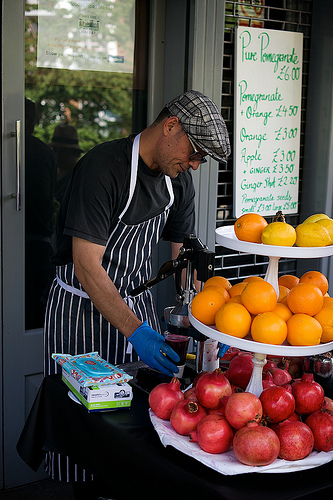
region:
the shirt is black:
[77, 162, 122, 235]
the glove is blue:
[127, 328, 184, 377]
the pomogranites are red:
[179, 373, 308, 462]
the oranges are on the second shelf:
[205, 276, 330, 344]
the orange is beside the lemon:
[224, 202, 295, 249]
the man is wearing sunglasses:
[184, 134, 213, 163]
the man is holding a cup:
[166, 331, 191, 368]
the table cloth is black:
[64, 409, 134, 458]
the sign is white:
[232, 21, 300, 214]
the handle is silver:
[0, 111, 29, 217]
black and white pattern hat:
[172, 91, 232, 162]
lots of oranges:
[200, 275, 331, 328]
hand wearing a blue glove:
[102, 309, 185, 371]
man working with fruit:
[109, 85, 195, 294]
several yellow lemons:
[277, 218, 332, 238]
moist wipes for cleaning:
[48, 349, 132, 391]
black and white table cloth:
[33, 385, 173, 489]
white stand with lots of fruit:
[206, 203, 319, 486]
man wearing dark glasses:
[154, 110, 220, 176]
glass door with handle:
[12, 29, 94, 239]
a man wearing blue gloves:
[128, 319, 179, 378]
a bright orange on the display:
[235, 212, 267, 242]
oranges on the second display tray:
[191, 269, 331, 342]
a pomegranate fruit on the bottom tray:
[145, 350, 328, 471]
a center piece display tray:
[145, 207, 326, 467]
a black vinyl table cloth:
[14, 407, 146, 490]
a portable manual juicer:
[129, 230, 209, 327]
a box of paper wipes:
[51, 349, 132, 409]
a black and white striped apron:
[44, 207, 171, 373]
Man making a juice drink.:
[43, 92, 232, 482]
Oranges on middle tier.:
[191, 270, 332, 356]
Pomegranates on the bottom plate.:
[147, 353, 332, 472]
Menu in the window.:
[233, 24, 305, 216]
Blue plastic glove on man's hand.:
[127, 321, 181, 379]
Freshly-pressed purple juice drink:
[164, 331, 190, 378]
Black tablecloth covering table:
[14, 364, 331, 498]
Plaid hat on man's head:
[165, 85, 228, 165]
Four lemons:
[262, 212, 331, 248]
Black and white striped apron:
[42, 133, 175, 484]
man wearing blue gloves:
[31, 79, 255, 486]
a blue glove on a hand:
[125, 320, 183, 384]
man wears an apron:
[30, 81, 240, 389]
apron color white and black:
[39, 150, 180, 387]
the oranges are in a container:
[193, 267, 330, 348]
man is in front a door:
[0, 1, 242, 496]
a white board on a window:
[229, 16, 306, 221]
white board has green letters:
[228, 20, 307, 217]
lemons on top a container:
[258, 198, 331, 252]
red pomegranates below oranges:
[150, 274, 330, 474]